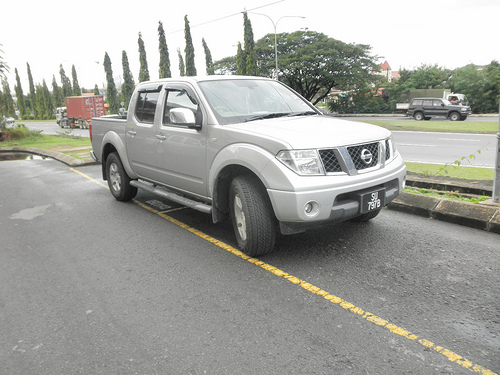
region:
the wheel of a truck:
[228, 168, 275, 260]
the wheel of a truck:
[104, 152, 136, 202]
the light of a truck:
[272, 145, 327, 177]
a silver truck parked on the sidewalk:
[80, 72, 407, 259]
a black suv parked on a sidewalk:
[405, 97, 475, 123]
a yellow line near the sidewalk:
[59, 161, 499, 374]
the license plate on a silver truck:
[355, 188, 390, 212]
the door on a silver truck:
[153, 79, 210, 190]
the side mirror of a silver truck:
[167, 105, 199, 127]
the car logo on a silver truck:
[359, 149, 375, 166]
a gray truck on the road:
[73, 55, 410, 265]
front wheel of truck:
[214, 163, 282, 263]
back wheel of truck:
[95, 142, 136, 207]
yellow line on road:
[138, 192, 492, 373]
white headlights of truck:
[278, 128, 402, 182]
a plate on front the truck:
[348, 185, 390, 220]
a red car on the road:
[51, 88, 113, 132]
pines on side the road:
[7, 9, 295, 146]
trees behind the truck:
[80, 22, 415, 266]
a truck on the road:
[87, 36, 451, 366]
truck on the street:
[67, 43, 472, 350]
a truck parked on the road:
[25, 15, 420, 307]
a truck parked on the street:
[73, 16, 468, 372]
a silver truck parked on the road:
[112, 41, 497, 308]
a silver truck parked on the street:
[99, 40, 381, 302]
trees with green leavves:
[128, 11, 293, 79]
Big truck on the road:
[54, 95, 108, 128]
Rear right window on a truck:
[132, 88, 164, 124]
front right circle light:
[304, 200, 317, 218]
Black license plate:
[357, 188, 388, 214]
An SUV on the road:
[407, 97, 470, 121]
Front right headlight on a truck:
[277, 145, 322, 176]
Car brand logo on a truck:
[356, 146, 375, 166]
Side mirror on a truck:
[167, 106, 194, 125]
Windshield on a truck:
[199, 80, 314, 121]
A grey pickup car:
[72, 82, 383, 272]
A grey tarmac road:
[19, 226, 374, 338]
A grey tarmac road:
[394, 207, 497, 370]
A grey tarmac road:
[420, 128, 498, 169]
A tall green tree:
[257, 28, 387, 103]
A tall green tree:
[230, 7, 272, 79]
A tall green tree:
[176, 10, 196, 80]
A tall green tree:
[145, 8, 184, 86]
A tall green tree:
[115, 42, 133, 107]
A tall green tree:
[86, 40, 118, 107]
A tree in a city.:
[100, 54, 120, 111]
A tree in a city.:
[131, 29, 150, 84]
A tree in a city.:
[154, 24, 175, 72]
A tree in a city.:
[175, 45, 180, 66]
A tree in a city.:
[180, 15, 197, 76]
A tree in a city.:
[198, 40, 214, 75]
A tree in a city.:
[234, 45, 246, 77]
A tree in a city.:
[238, 10, 260, 69]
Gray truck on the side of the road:
[1, 73, 498, 371]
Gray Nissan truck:
[87, 73, 409, 260]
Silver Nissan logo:
[358, 147, 373, 166]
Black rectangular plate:
[357, 184, 386, 215]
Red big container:
[64, 92, 105, 121]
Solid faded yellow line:
[66, 163, 496, 373]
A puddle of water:
[0, 149, 51, 162]